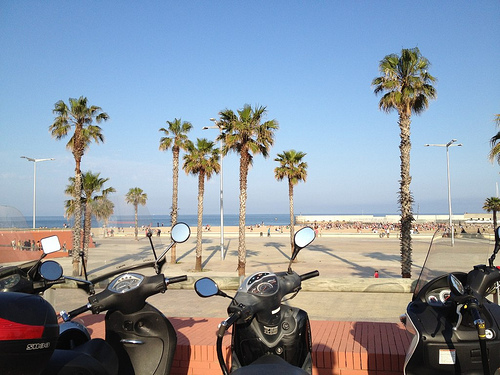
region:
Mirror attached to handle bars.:
[282, 210, 326, 270]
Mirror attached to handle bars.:
[141, 217, 218, 296]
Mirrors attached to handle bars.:
[36, 228, 73, 296]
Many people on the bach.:
[84, 200, 424, 235]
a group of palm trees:
[42, 50, 432, 245]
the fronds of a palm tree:
[217, 106, 273, 153]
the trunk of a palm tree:
[400, 138, 415, 265]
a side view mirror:
[290, 229, 316, 245]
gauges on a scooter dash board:
[246, 272, 278, 297]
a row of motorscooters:
[7, 231, 497, 362]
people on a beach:
[297, 210, 396, 232]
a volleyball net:
[103, 219, 140, 227]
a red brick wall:
[315, 320, 388, 373]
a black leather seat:
[226, 350, 301, 373]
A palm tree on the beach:
[370, 45, 436, 277]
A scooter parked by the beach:
[195, 225, 320, 370]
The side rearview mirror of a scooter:
[290, 225, 315, 245]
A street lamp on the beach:
[19, 154, 54, 229]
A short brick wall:
[55, 313, 418, 374]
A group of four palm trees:
[157, 103, 307, 275]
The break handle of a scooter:
[454, 300, 465, 332]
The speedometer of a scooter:
[256, 282, 273, 293]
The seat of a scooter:
[43, 337, 121, 372]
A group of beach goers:
[313, 220, 398, 234]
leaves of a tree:
[390, 52, 420, 67]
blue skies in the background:
[265, 49, 342, 104]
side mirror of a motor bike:
[298, 229, 312, 244]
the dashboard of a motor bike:
[113, 278, 143, 290]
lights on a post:
[22, 156, 48, 161]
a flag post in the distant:
[447, 159, 454, 184]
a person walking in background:
[268, 228, 273, 238]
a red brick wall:
[338, 336, 368, 346]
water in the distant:
[189, 217, 194, 223]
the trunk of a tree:
[401, 198, 412, 253]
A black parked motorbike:
[202, 227, 350, 374]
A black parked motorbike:
[65, 247, 157, 374]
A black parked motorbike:
[382, 267, 490, 355]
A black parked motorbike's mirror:
[284, 223, 318, 263]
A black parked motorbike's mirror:
[188, 267, 242, 308]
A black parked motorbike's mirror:
[152, 225, 206, 260]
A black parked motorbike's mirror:
[37, 251, 88, 289]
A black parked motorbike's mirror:
[32, 233, 79, 260]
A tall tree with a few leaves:
[374, 31, 449, 285]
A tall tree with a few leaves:
[275, 147, 309, 258]